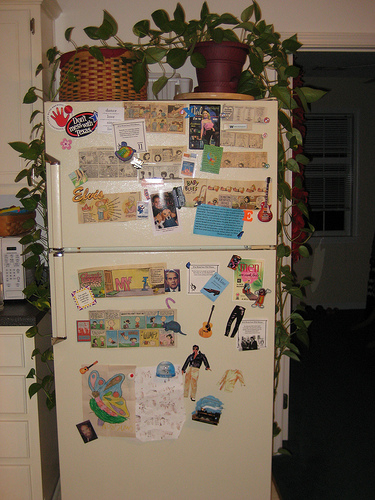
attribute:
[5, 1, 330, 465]
houseplant — leafy, green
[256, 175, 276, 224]
magnet — a guitar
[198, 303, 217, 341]
magnet — a guitar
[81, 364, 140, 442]
artwork — by kids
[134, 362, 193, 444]
artwork — by kids